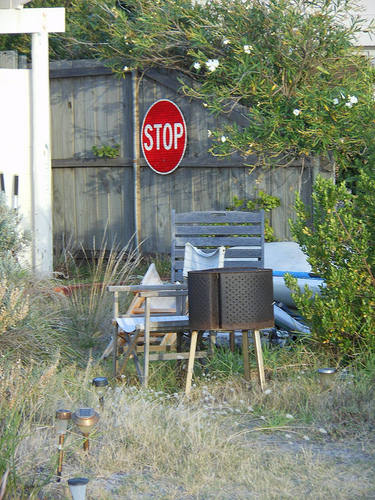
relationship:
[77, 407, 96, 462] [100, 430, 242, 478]
solar light on grass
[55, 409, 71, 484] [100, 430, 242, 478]
solar light on grass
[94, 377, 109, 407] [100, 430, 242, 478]
solar light on grass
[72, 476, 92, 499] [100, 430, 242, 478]
solar light on grass